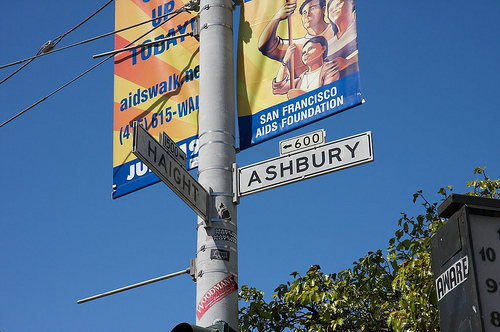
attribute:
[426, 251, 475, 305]
sticker — black , white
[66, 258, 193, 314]
rod — metal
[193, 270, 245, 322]
sticher — red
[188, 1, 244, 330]
pole — concrete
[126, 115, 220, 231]
sign — white, black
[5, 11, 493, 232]
sky — bright, blue, clear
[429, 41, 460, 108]
sky — blue,  background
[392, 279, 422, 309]
leaves — many tree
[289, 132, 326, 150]
number — 600 , black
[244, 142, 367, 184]
ashbury — black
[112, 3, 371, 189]
flyer — Aids Help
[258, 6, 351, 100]
image — human family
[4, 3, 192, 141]
wiring — electrical 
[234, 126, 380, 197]
signs — street 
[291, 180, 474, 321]
tree — growing 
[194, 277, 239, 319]
sticker — red 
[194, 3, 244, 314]
pole — concrete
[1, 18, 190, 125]
lines — electric 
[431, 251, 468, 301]
sticker — aware 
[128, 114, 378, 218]
sign — white street, black 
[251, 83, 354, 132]
text — some, white